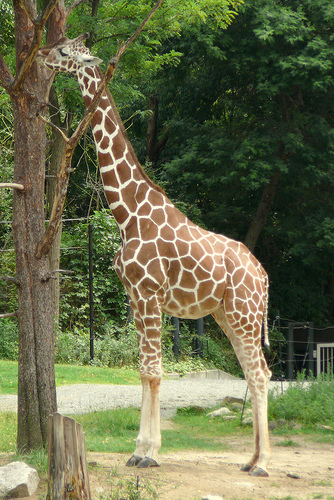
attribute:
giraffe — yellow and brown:
[28, 23, 302, 479]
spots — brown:
[155, 241, 254, 305]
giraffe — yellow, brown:
[18, 33, 289, 427]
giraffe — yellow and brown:
[41, 41, 270, 303]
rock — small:
[1, 459, 40, 498]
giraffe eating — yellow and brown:
[7, 19, 178, 117]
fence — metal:
[315, 341, 333, 379]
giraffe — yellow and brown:
[61, 47, 303, 480]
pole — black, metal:
[78, 203, 100, 370]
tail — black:
[257, 271, 274, 339]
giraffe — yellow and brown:
[132, 231, 204, 298]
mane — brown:
[93, 64, 171, 198]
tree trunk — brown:
[41, 411, 94, 497]